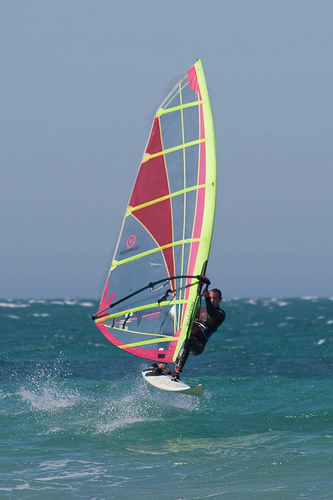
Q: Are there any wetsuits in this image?
A: Yes, there is a wetsuit.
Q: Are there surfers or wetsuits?
A: Yes, there is a wetsuit.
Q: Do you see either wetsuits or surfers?
A: Yes, there is a wetsuit.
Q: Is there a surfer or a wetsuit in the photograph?
A: Yes, there is a wetsuit.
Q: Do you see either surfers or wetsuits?
A: Yes, there is a wetsuit.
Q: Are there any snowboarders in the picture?
A: No, there are no snowboarders.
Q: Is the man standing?
A: Yes, the man is standing.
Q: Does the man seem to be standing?
A: Yes, the man is standing.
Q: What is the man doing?
A: The man is standing.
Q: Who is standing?
A: The man is standing.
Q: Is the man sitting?
A: No, the man is standing.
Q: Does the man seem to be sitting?
A: No, the man is standing.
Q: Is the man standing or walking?
A: The man is standing.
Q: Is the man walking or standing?
A: The man is standing.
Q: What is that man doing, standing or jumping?
A: The man is standing.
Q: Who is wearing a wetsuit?
A: The man is wearing a wetsuit.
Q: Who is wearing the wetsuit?
A: The man is wearing a wetsuit.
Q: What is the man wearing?
A: The man is wearing a wetsuit.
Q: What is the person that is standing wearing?
A: The man is wearing a wetsuit.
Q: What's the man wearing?
A: The man is wearing a wetsuit.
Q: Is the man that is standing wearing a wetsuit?
A: Yes, the man is wearing a wetsuit.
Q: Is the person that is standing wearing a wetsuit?
A: Yes, the man is wearing a wetsuit.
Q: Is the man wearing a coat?
A: No, the man is wearing a wetsuit.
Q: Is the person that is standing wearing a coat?
A: No, the man is wearing a wetsuit.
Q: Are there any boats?
A: No, there are no boats.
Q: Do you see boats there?
A: No, there are no boats.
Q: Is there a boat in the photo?
A: No, there are no boats.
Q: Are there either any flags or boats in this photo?
A: No, there are no boats or flags.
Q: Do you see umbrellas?
A: No, there are no umbrellas.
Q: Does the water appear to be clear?
A: Yes, the water is clear.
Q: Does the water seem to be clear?
A: Yes, the water is clear.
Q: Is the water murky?
A: No, the water is clear.